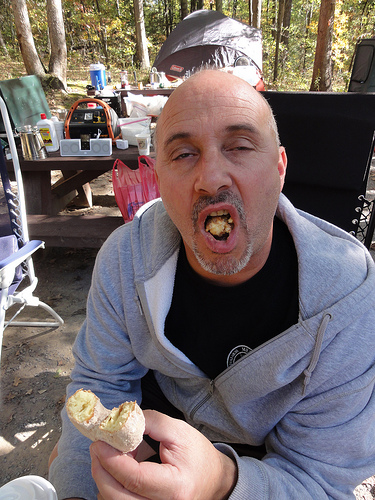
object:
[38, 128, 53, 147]
yellow label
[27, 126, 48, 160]
coffee pot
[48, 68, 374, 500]
man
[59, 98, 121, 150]
device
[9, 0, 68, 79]
tree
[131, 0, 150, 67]
tree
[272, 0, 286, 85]
tree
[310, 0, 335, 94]
tree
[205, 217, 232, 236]
donut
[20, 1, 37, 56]
outside light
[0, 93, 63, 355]
chair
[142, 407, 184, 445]
thumb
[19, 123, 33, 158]
kettle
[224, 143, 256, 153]
left eye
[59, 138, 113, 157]
ipod speaker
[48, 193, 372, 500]
jacket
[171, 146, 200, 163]
right eye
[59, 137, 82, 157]
speakers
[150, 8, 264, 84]
camping tent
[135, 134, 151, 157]
cup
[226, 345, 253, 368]
logo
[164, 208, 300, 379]
black shirt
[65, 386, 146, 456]
donut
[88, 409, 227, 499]
hand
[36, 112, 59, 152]
bottle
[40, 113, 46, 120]
cap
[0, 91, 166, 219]
table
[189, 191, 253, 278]
mustache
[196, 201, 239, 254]
mouth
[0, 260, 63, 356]
base